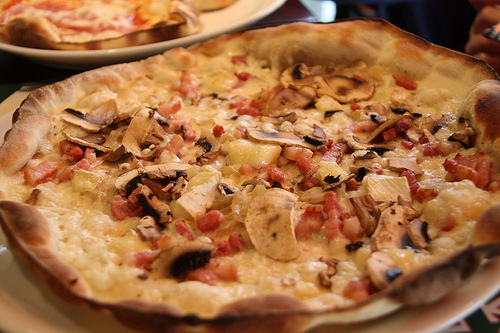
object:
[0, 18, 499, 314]
pizza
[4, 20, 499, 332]
plate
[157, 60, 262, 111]
cheese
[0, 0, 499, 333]
table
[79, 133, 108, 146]
mushrooms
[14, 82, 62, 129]
bread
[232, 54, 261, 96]
spices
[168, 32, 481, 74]
crust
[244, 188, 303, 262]
tomatoes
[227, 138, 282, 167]
pineapple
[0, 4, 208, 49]
pizza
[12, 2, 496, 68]
background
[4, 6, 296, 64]
plate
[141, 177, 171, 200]
meat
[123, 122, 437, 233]
toppings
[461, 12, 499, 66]
hand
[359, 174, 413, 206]
chicken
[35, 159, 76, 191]
topping